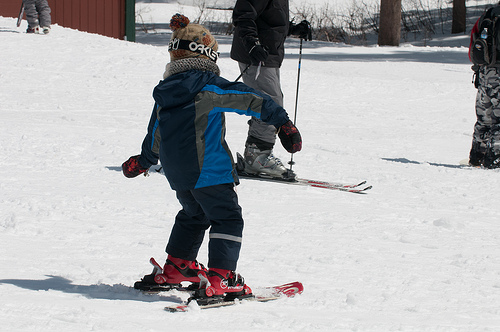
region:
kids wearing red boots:
[102, 15, 328, 308]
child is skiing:
[111, 6, 329, 323]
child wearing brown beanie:
[149, 8, 225, 61]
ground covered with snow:
[295, 203, 480, 328]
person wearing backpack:
[457, 1, 497, 168]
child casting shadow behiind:
[6, 18, 346, 300]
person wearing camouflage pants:
[451, 46, 498, 175]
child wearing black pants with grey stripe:
[86, 13, 294, 311]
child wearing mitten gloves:
[103, 10, 300, 299]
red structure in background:
[0, 4, 144, 52]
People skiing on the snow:
[8, 5, 493, 330]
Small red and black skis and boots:
[127, 242, 320, 319]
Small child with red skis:
[91, 7, 316, 319]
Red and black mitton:
[263, 112, 310, 168]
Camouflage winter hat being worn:
[143, 5, 235, 66]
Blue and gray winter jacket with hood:
[108, 62, 293, 202]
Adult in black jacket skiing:
[222, 2, 374, 197]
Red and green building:
[53, 2, 137, 39]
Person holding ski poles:
[268, 2, 340, 177]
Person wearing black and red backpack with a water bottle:
[458, 0, 495, 192]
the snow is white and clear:
[325, 213, 406, 296]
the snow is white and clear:
[339, 268, 379, 326]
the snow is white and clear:
[364, 221, 443, 323]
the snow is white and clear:
[294, 156, 439, 290]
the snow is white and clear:
[385, 166, 455, 310]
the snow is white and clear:
[338, 192, 425, 319]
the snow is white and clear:
[364, 106, 489, 325]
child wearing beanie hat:
[161, 10, 223, 75]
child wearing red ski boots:
[126, 239, 323, 321]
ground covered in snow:
[330, 213, 485, 318]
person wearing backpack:
[458, 10, 499, 72]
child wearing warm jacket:
[93, 14, 341, 319]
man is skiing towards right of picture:
[125, 0, 377, 200]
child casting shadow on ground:
[5, 18, 381, 318]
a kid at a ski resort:
[100, 5, 497, 295]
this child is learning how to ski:
[43, 0, 343, 315]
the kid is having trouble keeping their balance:
[90, 17, 330, 319]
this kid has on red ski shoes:
[96, 215, 359, 324]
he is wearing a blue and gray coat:
[97, 50, 321, 225]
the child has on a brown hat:
[132, 14, 247, 92]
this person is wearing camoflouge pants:
[435, 1, 495, 166]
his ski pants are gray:
[238, 40, 388, 203]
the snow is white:
[7, 10, 488, 233]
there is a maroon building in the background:
[10, 5, 152, 82]